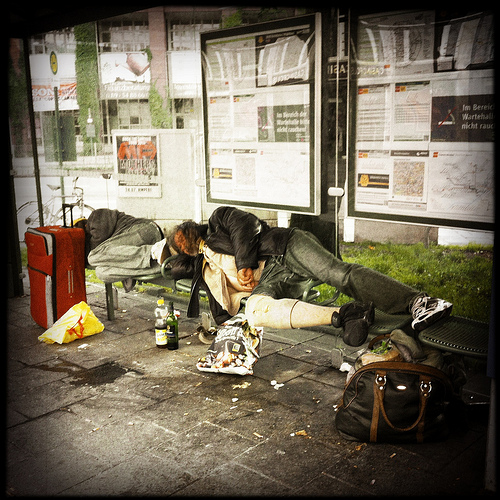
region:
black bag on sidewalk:
[334, 352, 457, 474]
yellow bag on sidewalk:
[29, 305, 116, 359]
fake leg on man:
[216, 287, 371, 350]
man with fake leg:
[224, 292, 380, 353]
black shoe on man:
[316, 287, 378, 343]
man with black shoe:
[324, 301, 390, 336]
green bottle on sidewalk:
[164, 290, 191, 393]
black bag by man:
[212, 295, 264, 410]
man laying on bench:
[212, 268, 448, 351]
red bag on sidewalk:
[21, 219, 86, 325]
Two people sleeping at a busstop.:
[29, 191, 481, 371]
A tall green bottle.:
[163, 298, 182, 350]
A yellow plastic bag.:
[37, 302, 103, 348]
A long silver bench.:
[39, 229, 498, 403]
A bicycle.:
[11, 174, 98, 233]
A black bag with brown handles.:
[321, 346, 462, 445]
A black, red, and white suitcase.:
[27, 203, 91, 332]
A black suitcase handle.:
[60, 202, 75, 229]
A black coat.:
[164, 207, 298, 328]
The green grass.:
[17, 227, 499, 350]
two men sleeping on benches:
[46, 195, 428, 363]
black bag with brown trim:
[331, 358, 446, 441]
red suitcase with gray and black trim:
[23, 226, 87, 332]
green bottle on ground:
[158, 300, 178, 352]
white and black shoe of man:
[402, 291, 456, 331]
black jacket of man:
[173, 198, 286, 298]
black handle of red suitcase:
[54, 199, 76, 221]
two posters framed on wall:
[193, 4, 499, 222]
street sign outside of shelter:
[42, 44, 75, 222]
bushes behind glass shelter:
[110, 217, 487, 320]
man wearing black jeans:
[206, 228, 463, 371]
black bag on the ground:
[340, 345, 464, 448]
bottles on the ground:
[138, 286, 180, 356]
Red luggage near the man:
[23, 203, 104, 358]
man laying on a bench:
[163, 218, 426, 386]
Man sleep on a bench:
[71, 202, 166, 291]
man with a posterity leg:
[226, 290, 396, 355]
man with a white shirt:
[199, 230, 266, 319]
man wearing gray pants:
[88, 214, 150, 270]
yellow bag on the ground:
[44, 292, 112, 362]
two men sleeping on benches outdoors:
[70, 200, 456, 362]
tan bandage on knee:
[247, 289, 304, 335]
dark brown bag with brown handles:
[329, 351, 461, 451]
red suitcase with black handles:
[22, 193, 91, 333]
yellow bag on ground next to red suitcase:
[30, 296, 106, 350]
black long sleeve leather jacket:
[171, 204, 295, 325]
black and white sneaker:
[399, 291, 454, 333]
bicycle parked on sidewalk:
[14, 163, 101, 245]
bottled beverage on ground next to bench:
[163, 299, 181, 352]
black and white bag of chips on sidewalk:
[194, 310, 268, 382]